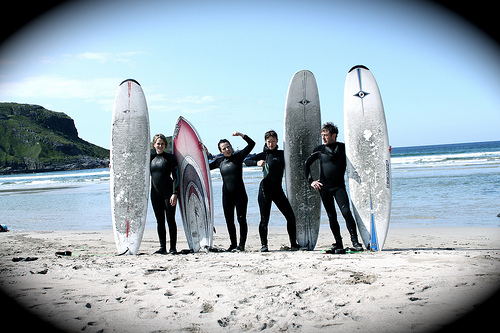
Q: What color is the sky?
A: Blue.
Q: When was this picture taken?
A: Daytime.